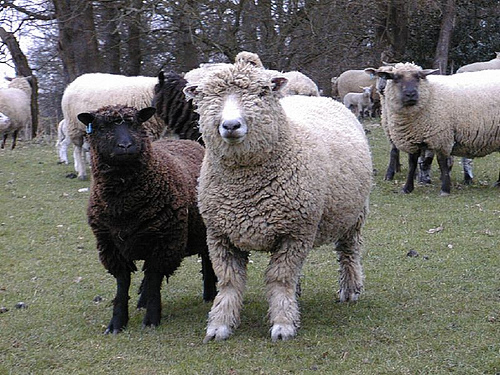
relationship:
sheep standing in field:
[375, 61, 499, 196] [9, 177, 486, 372]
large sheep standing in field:
[182, 62, 374, 342] [9, 177, 486, 372]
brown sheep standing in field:
[76, 105, 216, 335] [9, 177, 486, 372]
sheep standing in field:
[59, 67, 188, 178] [9, 177, 486, 372]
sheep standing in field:
[9, 67, 34, 169] [9, 177, 486, 372]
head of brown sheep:
[77, 103, 158, 175] [76, 105, 216, 335]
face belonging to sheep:
[391, 69, 420, 109] [367, 60, 485, 196]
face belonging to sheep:
[153, 68, 185, 92] [61, 72, 184, 172]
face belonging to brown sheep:
[95, 110, 139, 149] [76, 105, 216, 335]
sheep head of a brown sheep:
[177, 54, 292, 176] [76, 105, 216, 335]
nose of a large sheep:
[220, 118, 242, 130] [182, 62, 374, 342]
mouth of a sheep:
[220, 129, 250, 147] [179, 37, 399, 347]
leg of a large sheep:
[263, 234, 316, 318] [182, 62, 374, 342]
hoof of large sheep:
[269, 309, 306, 344] [182, 62, 374, 342]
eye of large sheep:
[254, 87, 269, 103] [182, 62, 374, 342]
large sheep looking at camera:
[182, 62, 374, 342] [483, 365, 484, 368]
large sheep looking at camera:
[182, 62, 374, 342] [480, 361, 484, 364]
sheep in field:
[375, 61, 499, 196] [383, 201, 498, 373]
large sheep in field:
[182, 62, 374, 342] [383, 201, 498, 373]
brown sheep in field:
[76, 105, 216, 335] [383, 201, 498, 373]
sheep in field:
[335, 69, 372, 88] [383, 201, 498, 373]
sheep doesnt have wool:
[375, 61, 499, 196] [446, 85, 486, 121]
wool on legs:
[446, 85, 486, 121] [387, 133, 475, 193]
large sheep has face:
[182, 62, 374, 342] [204, 81, 254, 148]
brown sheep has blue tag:
[76, 105, 216, 335] [85, 123, 93, 134]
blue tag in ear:
[85, 123, 93, 134] [73, 110, 98, 130]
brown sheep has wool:
[154, 71, 206, 138] [125, 188, 182, 228]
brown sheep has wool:
[72, 104, 216, 331] [125, 188, 182, 228]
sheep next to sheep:
[338, 82, 375, 120] [332, 61, 384, 101]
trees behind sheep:
[29, 10, 493, 121] [78, 99, 226, 329]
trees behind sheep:
[29, 10, 493, 121] [191, 62, 371, 337]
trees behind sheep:
[29, 10, 493, 121] [378, 56, 488, 194]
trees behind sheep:
[29, 10, 493, 121] [54, 56, 171, 177]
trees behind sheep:
[29, 10, 493, 121] [5, 70, 32, 142]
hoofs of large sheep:
[197, 326, 304, 346] [182, 62, 374, 342]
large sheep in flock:
[182, 62, 374, 342] [1, 48, 498, 348]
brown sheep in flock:
[76, 105, 216, 335] [1, 48, 498, 348]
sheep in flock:
[361, 55, 496, 200] [1, 48, 498, 348]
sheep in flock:
[52, 66, 176, 174] [1, 48, 498, 348]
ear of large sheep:
[259, 66, 289, 94] [182, 62, 374, 342]